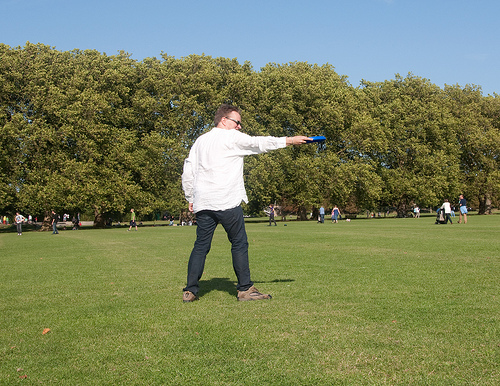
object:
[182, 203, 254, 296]
blue jeans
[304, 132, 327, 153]
frisbee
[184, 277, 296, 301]
shadow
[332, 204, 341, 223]
person walking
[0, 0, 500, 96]
sky is blue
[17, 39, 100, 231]
tall tree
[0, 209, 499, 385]
green grass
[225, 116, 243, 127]
black glasses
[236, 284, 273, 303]
man has shoe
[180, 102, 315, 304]
man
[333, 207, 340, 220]
dress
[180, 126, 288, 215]
shirt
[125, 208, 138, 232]
person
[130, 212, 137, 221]
green shirt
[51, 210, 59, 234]
person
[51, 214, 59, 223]
black shirt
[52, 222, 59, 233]
blue jeans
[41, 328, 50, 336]
brown leaf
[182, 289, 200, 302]
shoe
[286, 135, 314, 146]
hand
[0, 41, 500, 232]
tree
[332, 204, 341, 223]
woman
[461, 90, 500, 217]
green trees